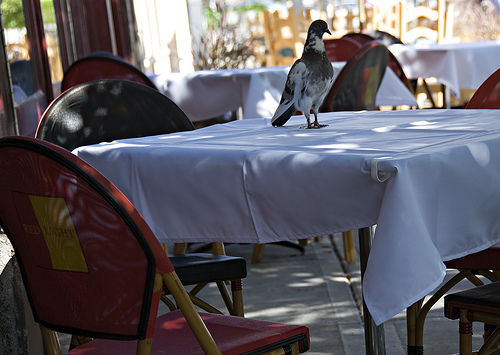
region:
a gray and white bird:
[270, 18, 335, 130]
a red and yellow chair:
[3, 133, 312, 350]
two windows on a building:
[3, 26, 65, 108]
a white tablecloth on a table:
[70, 108, 496, 328]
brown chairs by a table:
[244, 2, 454, 106]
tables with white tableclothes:
[72, 40, 499, 327]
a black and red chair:
[33, 75, 249, 320]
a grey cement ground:
[53, 225, 499, 350]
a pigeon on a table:
[270, 18, 335, 130]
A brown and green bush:
[189, 3, 266, 70]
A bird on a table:
[254, 10, 353, 156]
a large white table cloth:
[63, 119, 498, 318]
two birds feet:
[286, 91, 330, 128]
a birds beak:
[323, 23, 330, 34]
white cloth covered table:
[399, 30, 497, 115]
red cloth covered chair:
[17, 124, 332, 353]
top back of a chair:
[26, 51, 196, 180]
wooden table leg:
[349, 217, 388, 353]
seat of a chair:
[176, 248, 252, 325]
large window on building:
[0, 0, 140, 127]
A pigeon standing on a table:
[217, 6, 432, 173]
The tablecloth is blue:
[85, 11, 480, 297]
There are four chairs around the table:
[8, 36, 498, 346]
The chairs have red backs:
[2, 112, 233, 354]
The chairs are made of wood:
[0, 140, 325, 351]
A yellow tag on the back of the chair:
[11, 180, 118, 296]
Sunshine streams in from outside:
[130, 0, 495, 55]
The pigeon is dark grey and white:
[235, 5, 356, 131]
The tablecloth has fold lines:
[55, 35, 475, 315]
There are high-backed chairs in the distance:
[205, 5, 466, 70]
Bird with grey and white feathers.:
[270, 13, 342, 132]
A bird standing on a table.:
[258, 8, 361, 150]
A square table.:
[70, 97, 488, 303]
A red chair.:
[1, 120, 306, 352]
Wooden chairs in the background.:
[332, 0, 466, 41]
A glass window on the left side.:
[3, 7, 59, 134]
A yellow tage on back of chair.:
[23, 191, 93, 278]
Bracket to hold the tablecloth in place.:
[356, 135, 413, 197]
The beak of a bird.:
[295, 9, 343, 55]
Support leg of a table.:
[340, 221, 402, 352]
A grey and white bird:
[261, 11, 339, 138]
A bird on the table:
[265, 12, 343, 153]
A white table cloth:
[112, 123, 497, 250]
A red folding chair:
[1, 131, 313, 352]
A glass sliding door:
[1, 2, 142, 142]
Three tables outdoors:
[80, 28, 497, 305]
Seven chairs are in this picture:
[7, 36, 498, 351]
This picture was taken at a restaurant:
[4, 2, 498, 353]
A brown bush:
[188, 16, 270, 81]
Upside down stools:
[254, 1, 456, 83]